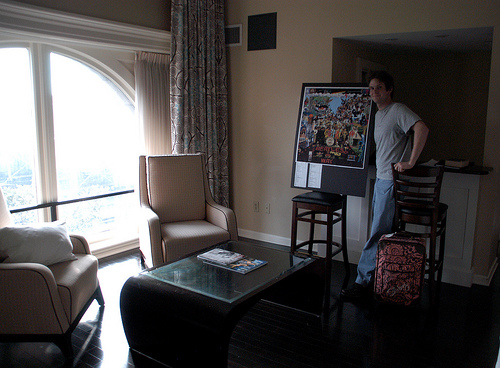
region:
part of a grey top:
[379, 112, 400, 172]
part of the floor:
[378, 304, 416, 327]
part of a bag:
[383, 257, 415, 299]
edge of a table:
[228, 311, 245, 330]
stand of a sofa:
[53, 335, 81, 362]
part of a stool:
[298, 203, 335, 245]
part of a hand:
[390, 153, 416, 170]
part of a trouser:
[365, 197, 387, 237]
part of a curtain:
[217, 179, 229, 206]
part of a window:
[72, 161, 109, 196]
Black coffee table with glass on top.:
[118, 236, 327, 366]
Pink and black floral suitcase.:
[376, 229, 427, 309]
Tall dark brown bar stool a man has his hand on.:
[386, 159, 450, 298]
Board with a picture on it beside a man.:
[290, 81, 376, 198]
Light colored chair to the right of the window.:
[131, 153, 238, 269]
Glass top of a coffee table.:
[141, 238, 310, 305]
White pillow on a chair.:
[1, 221, 78, 268]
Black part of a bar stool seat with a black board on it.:
[291, 186, 345, 208]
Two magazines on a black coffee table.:
[191, 246, 268, 276]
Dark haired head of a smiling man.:
[364, 71, 396, 107]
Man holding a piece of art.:
[118, 20, 473, 356]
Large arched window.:
[2, 4, 146, 266]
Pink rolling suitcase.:
[372, 220, 439, 318]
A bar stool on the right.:
[386, 150, 451, 296]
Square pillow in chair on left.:
[8, 215, 85, 270]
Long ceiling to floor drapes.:
[156, 2, 245, 247]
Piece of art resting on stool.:
[284, 67, 379, 289]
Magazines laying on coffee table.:
[181, 234, 279, 294]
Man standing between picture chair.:
[293, 63, 450, 233]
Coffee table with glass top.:
[109, 225, 354, 365]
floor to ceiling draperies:
[167, 0, 233, 211]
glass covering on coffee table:
[138, 238, 318, 303]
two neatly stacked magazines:
[194, 246, 269, 278]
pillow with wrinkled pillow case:
[0, 218, 77, 265]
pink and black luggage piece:
[371, 229, 428, 304]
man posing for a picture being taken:
[288, 75, 430, 296]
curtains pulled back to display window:
[135, 48, 189, 155]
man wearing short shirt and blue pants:
[354, 76, 429, 295]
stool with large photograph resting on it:
[288, 77, 375, 277]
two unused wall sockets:
[249, 198, 272, 217]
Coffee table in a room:
[116, 235, 308, 312]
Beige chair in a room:
[121, 146, 239, 263]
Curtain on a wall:
[167, 10, 257, 232]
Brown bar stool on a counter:
[281, 177, 366, 288]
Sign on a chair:
[294, 72, 384, 221]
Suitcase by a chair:
[366, 228, 419, 309]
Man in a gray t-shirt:
[341, 73, 423, 255]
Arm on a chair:
[388, 113, 428, 185]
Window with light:
[9, 46, 172, 246]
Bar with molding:
[331, 146, 498, 287]